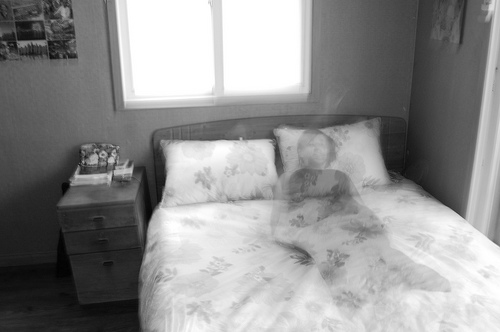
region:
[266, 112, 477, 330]
shadowy figure on bed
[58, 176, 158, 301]
nighstand beside bed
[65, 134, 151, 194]
items on top of nightstand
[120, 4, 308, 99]
window above the bed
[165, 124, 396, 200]
two pillows on the bed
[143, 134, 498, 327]
bed made with printed white sheets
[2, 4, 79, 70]
pictures on the wall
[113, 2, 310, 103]
windowsill of window above bed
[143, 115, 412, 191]
headboard of bed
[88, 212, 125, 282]
drawer pulls on nightstand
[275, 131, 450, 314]
shadowy figure of a woman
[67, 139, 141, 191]
stuff sitting on top of nightstand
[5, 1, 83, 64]
collage of pictures on wall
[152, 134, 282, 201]
pillow of the left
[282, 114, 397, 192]
pillow on the right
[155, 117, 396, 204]
two pillows propped on the bed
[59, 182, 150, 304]
wooden nightstand by bed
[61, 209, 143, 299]
three drawers of the nightstand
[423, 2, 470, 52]
artwork on the wall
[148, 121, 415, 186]
headboard of the bed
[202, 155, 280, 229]
part of a pillow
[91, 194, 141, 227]
part of a drawer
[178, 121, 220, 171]
part of a pillow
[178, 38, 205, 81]
part of a window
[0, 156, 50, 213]
part of a wall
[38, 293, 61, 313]
part of a floor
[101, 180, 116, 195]
edge of a cupboard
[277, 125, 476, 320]
shadowy figure on the bed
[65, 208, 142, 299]
drawers of the nightstand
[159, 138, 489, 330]
white sheets with pattern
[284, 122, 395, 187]
pillow with shadowy person's head on it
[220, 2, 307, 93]
right window pane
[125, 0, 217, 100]
left window pane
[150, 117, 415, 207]
headboard with pillows propped against it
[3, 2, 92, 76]
various photos on the wall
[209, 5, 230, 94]
window divider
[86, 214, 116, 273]
three drawer handles on nightstand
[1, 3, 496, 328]
An image of a bedroom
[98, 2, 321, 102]
Window showing daytime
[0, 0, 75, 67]
collage of photos on wall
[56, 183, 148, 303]
Nightstand has three drawers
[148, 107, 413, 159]
A simple headboard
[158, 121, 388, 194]
two pillows on the bed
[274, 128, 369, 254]
Opacity image of woman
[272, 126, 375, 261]
Woman is laying on bed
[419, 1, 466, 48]
a poster on wall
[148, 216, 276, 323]
Flower and white bedding